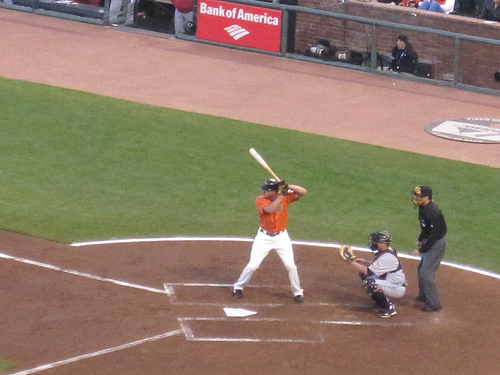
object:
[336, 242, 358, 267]
mit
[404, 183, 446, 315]
umpire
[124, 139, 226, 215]
field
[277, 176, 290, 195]
batter's hands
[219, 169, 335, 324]
man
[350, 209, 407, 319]
man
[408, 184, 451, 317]
man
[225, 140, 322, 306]
man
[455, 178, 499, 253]
grass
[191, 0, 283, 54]
banner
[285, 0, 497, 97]
fence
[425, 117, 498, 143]
sign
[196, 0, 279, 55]
sign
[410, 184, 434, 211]
mask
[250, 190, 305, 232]
orange shirt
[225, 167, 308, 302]
man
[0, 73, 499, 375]
baseball field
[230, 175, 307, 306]
man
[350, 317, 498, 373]
field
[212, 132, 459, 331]
men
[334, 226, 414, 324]
catcher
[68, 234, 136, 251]
line edge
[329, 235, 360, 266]
gear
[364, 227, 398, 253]
gear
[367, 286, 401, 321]
gear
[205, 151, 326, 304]
man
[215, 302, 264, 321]
home plate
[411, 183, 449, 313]
umpire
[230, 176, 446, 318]
men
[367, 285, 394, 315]
shin guards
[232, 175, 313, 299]
batter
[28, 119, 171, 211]
field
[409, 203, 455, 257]
shirt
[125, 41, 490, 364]
baseball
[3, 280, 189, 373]
ground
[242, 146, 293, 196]
baseball bat